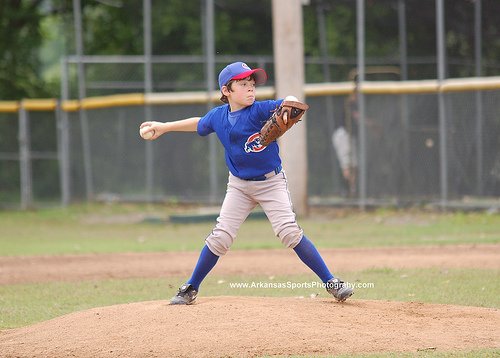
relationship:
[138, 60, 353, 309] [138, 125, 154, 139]
boy throwing ball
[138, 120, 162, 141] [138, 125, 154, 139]
hand gripping ball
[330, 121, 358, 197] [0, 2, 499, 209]
person standing behind fence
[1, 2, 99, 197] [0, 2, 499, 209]
tree behind fence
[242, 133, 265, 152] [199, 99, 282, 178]
logo on jersey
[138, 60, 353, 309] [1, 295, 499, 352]
boy on pitcher's mound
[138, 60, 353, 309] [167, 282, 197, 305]
boy wearing a shoe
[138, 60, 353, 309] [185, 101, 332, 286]
boy wearing a uniform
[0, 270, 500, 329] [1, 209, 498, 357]
grass on field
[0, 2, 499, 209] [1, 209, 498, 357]
fence behind field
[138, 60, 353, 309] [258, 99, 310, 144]
boy has a baseball mitt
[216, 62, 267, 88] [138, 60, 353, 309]
hat on boy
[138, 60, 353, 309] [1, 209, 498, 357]
boy standing on field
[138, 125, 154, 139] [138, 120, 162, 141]
ball in hand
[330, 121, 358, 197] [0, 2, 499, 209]
person standing by fence